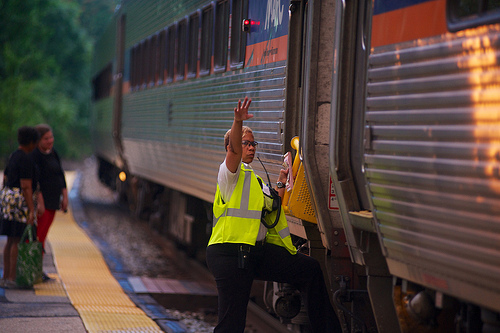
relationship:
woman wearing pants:
[204, 96, 343, 333] [202, 239, 333, 326]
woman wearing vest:
[204, 96, 343, 333] [205, 160, 297, 260]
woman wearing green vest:
[204, 96, 343, 333] [207, 162, 298, 255]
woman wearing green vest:
[207, 93, 340, 331] [203, 157, 302, 257]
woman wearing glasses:
[207, 93, 340, 331] [238, 137, 258, 147]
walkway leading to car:
[126, 275, 220, 299] [90, 0, 500, 333]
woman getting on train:
[204, 96, 343, 333] [68, 7, 487, 299]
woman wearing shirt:
[32, 124, 71, 279] [39, 150, 67, 210]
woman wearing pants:
[32, 124, 71, 279] [37, 210, 55, 243]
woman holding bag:
[0, 125, 37, 292] [15, 222, 42, 289]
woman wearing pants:
[0, 125, 37, 292] [200, 238, 258, 321]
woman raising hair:
[207, 93, 340, 331] [223, 127, 252, 148]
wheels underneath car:
[118, 179, 203, 234] [120, 2, 315, 272]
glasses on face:
[238, 136, 257, 150] [234, 128, 260, 167]